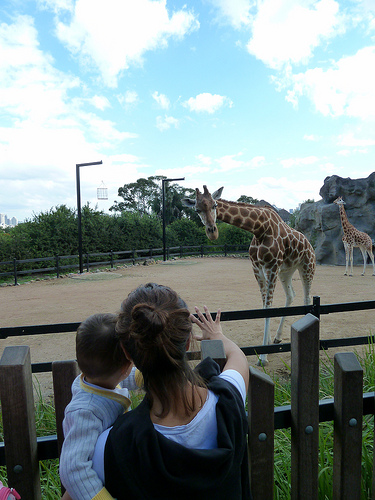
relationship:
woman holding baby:
[60, 282, 251, 498] [55, 311, 149, 498]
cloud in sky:
[52, 0, 199, 90] [2, 2, 373, 227]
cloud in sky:
[240, 0, 345, 72] [2, 2, 373, 227]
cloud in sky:
[284, 43, 372, 119] [2, 2, 373, 227]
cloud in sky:
[79, 110, 136, 147] [2, 2, 373, 227]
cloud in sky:
[52, 0, 199, 90] [49, 25, 374, 179]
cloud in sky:
[170, 82, 246, 116] [1, 3, 371, 178]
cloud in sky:
[292, 47, 374, 123] [2, 2, 373, 227]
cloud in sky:
[188, 91, 225, 114] [2, 2, 373, 227]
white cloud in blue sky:
[330, 127, 374, 154] [183, 57, 249, 91]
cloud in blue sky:
[292, 47, 374, 123] [183, 57, 249, 91]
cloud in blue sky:
[79, 110, 136, 147] [183, 57, 249, 91]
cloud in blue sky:
[52, 0, 199, 90] [183, 57, 249, 91]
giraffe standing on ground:
[184, 183, 323, 366] [75, 251, 372, 369]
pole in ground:
[71, 158, 106, 272] [0, 246, 375, 495]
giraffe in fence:
[184, 183, 323, 366] [0, 296, 375, 500]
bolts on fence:
[347, 415, 358, 427] [2, 242, 220, 278]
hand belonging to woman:
[186, 304, 226, 343] [89, 279, 252, 497]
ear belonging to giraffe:
[178, 196, 195, 206] [184, 183, 323, 366]